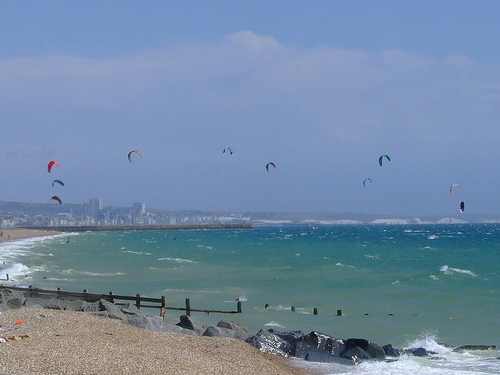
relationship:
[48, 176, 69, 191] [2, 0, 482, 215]
kite in sky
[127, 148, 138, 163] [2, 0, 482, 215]
kite in sky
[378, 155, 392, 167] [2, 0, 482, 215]
kite in sky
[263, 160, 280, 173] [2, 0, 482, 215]
kite in sky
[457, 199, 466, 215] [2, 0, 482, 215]
kite in sky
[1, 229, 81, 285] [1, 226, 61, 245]
waves washing ashore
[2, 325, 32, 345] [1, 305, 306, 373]
person laying in sand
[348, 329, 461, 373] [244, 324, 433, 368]
waves crashing on rocks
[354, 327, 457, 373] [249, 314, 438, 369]
waves crashing on rocks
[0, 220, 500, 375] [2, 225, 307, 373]
ocean near a beach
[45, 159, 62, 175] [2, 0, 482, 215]
kite in sky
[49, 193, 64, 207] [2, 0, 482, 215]
kite in sky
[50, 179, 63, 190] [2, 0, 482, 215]
kite in sky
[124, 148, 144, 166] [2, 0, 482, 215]
kite in sky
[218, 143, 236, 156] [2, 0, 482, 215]
kite in sky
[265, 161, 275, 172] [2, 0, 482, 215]
kite in sky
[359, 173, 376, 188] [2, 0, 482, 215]
kite in sky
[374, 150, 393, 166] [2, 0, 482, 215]
kite in sky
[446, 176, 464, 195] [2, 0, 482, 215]
kite in sky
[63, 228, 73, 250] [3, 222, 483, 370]
people in water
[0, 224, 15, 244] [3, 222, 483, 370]
people near water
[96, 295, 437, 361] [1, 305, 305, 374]
rocks along sand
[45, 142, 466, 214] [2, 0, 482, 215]
kites flying in sky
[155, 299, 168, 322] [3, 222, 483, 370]
person standing in water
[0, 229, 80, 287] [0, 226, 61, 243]
waves crashing on ashore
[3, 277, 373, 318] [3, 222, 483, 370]
posts going in to water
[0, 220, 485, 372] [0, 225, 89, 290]
ocean with many waves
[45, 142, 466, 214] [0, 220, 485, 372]
kites flying over ocean